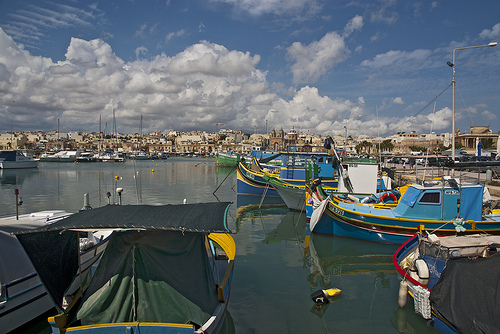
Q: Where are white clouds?
A: In the sky.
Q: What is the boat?
A: Blue.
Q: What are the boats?
A: Colorful.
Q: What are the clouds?
A: White and fluffy.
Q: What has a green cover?
A: The boat.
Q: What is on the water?
A: Many boats.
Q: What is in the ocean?
A: Many boats.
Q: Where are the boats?
A: On the water.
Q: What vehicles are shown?
A: Boats.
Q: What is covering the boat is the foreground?
A: Green tarp.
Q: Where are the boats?
A: Docks.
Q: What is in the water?
A: Boats.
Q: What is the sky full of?
A: Clouds.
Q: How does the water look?
A: Green.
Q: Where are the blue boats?
A: In the water.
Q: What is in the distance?
A: Many buildings.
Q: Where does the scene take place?
A: Outdoors at a boat pier.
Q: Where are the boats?
A: In the marina.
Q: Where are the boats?
A: In the harbor.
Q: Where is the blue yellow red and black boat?
A: In the water.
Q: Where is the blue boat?
A: In the marina.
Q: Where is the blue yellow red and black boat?
A: In the marina.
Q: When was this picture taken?
A: During the day.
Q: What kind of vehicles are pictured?
A: Boats.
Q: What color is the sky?
A: Blue.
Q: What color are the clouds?
A: White.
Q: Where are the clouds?
A: In the sky.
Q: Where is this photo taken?
A: In a harbor.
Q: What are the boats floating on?
A: Water.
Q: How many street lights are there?
A: One.